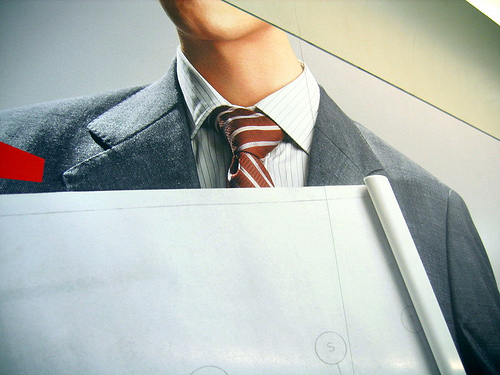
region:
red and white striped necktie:
[218, 104, 285, 187]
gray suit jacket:
[11, 81, 488, 367]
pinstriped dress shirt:
[174, 47, 321, 203]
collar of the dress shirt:
[177, 44, 317, 141]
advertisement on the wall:
[2, 4, 496, 371]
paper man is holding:
[4, 187, 461, 374]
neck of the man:
[172, 35, 291, 97]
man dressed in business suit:
[3, 5, 499, 372]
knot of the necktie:
[221, 111, 273, 151]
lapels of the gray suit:
[77, 94, 404, 199]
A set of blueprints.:
[4, 173, 470, 374]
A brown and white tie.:
[201, 95, 288, 187]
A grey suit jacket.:
[2, 60, 498, 366]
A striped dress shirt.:
[175, 47, 327, 187]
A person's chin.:
[156, 3, 278, 44]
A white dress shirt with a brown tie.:
[174, 41, 324, 187]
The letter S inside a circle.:
[311, 328, 349, 370]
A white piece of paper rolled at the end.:
[2, 170, 461, 371]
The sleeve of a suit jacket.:
[442, 183, 497, 373]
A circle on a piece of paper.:
[315, 328, 349, 366]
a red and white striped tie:
[213, 106, 287, 189]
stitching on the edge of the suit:
[58, 81, 150, 190]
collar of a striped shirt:
[177, 45, 230, 137]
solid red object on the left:
[0, 138, 45, 178]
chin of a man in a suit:
[170, 0, 262, 39]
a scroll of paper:
[0, 174, 465, 374]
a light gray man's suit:
[0, 83, 498, 374]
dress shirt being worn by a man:
[172, 50, 317, 190]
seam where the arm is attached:
[442, 186, 457, 337]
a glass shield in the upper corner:
[227, 0, 499, 141]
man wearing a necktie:
[206, 108, 286, 184]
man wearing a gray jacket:
[319, 116, 499, 309]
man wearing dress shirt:
[155, 59, 314, 194]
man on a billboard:
[47, 13, 474, 366]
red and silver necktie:
[193, 87, 297, 199]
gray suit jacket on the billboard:
[296, 90, 498, 350]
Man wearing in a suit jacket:
[11, 58, 496, 282]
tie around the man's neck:
[213, 104, 280, 193]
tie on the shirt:
[219, 109, 277, 191]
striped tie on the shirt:
[221, 112, 276, 189]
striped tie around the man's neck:
[206, 105, 281, 192]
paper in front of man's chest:
[3, 169, 478, 374]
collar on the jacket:
[316, 92, 387, 186]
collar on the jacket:
[64, 64, 198, 184]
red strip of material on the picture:
[2, 138, 52, 185]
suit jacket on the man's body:
[1, 79, 498, 374]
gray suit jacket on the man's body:
[1, 89, 495, 374]